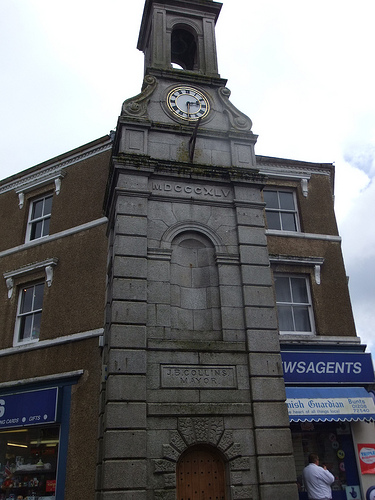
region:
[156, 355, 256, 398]
J.B. Collins Mayor engraved in stone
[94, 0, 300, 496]
the building is a clock tower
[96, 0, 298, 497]
the clock tower is built of stone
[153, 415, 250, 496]
the wooden door is recessed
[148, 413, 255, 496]
the stone arch for the door is recessed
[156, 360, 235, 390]
a plaque is above the door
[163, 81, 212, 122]
the clock has Roman numerals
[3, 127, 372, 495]
a building is built around the clock tower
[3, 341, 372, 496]
shops are next to the tower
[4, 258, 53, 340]
the window has white panes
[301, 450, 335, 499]
a man is standing in front of a shop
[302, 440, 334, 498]
Man in front of building.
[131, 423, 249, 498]
Wooden door on stone building.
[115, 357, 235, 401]
Sign that says j.b. collins mayor.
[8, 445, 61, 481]
Items in a window.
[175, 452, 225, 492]
Black bolts in wooden door.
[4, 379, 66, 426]
Blue and white sign.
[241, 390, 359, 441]
Bkue and white sign that says guardian.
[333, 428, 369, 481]
Red white and blue sign.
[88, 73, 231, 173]
Clock face on a building.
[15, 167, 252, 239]
Roman numerals on a building.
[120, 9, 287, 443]
Clock tower in front of a building.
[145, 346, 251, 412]
Stone engraving with government official's name.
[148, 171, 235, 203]
Roman numeral denoting the year 1845.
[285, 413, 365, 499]
Man standing in front of a shop.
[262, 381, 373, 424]
Blue and white awning.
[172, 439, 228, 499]
Wooden door with iron rivets.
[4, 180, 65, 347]
Windows on the second and third story of a building.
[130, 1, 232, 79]
Top of a bell tower.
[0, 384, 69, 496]
Gift shop with blue sign.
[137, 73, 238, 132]
Gold-rimmed clock with roman numerals.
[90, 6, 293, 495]
Clock tower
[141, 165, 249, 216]
Roman numerals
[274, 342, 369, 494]
Newsagents store front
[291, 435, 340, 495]
Man standing in front of newsagents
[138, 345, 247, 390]
Stone plaque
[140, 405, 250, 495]
Wooden door under a stone archway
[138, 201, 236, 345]
Small stone alcove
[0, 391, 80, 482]
Gifts shop with blue sign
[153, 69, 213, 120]
Gold-trimmed clock with black numerals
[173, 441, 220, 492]
A wooden door with holes in it